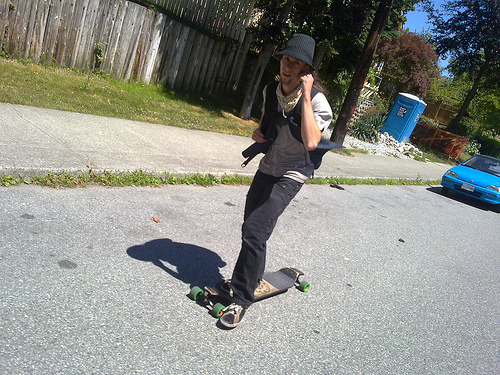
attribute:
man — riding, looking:
[214, 29, 333, 337]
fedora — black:
[274, 33, 324, 66]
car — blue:
[441, 155, 499, 208]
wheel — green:
[298, 280, 313, 293]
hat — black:
[273, 32, 318, 70]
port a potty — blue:
[379, 91, 426, 142]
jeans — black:
[232, 167, 303, 306]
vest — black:
[259, 80, 321, 176]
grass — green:
[0, 55, 254, 138]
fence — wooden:
[2, 3, 260, 104]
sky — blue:
[403, 1, 483, 78]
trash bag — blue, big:
[380, 92, 426, 141]